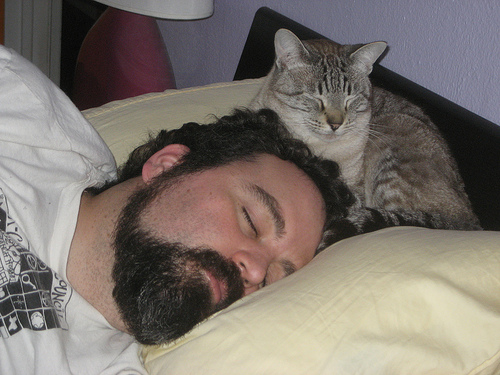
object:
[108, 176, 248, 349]
beard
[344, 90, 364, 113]
eye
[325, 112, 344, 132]
nose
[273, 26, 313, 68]
ear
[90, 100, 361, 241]
hair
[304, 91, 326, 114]
eye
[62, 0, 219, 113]
lamp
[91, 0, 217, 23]
shade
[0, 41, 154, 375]
shirt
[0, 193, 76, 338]
writing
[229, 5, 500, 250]
headboard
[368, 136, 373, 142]
whiskers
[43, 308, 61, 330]
square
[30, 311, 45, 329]
square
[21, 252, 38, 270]
square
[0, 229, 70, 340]
square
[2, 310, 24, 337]
square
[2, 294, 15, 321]
square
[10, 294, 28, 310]
square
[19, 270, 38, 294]
square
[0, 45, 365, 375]
man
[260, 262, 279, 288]
eyes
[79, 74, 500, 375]
pillow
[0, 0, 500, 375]
bed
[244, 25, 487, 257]
cat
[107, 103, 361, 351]
head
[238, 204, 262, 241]
eyes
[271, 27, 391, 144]
head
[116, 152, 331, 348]
face